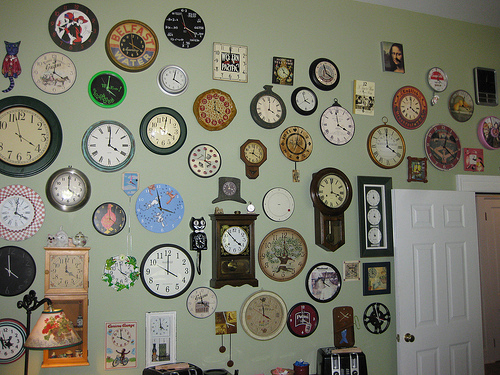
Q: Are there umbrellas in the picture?
A: No, there are no umbrellas.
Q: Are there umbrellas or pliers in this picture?
A: No, there are no umbrellas or pliers.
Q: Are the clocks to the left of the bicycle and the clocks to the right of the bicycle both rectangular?
A: Yes, both the clocks and the clocks are rectangular.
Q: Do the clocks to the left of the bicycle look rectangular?
A: Yes, the clocks are rectangular.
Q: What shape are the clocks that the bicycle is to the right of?
A: The clocks are rectangular.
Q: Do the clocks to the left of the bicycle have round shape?
A: No, the clocks are rectangular.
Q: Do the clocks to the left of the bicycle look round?
A: No, the clocks are rectangular.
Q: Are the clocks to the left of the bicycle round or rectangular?
A: The clocks are rectangular.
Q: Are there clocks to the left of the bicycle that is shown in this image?
A: Yes, there are clocks to the left of the bicycle.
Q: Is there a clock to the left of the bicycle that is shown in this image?
A: Yes, there are clocks to the left of the bicycle.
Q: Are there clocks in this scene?
A: Yes, there is a clock.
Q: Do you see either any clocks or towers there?
A: Yes, there is a clock.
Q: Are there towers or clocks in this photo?
A: Yes, there is a clock.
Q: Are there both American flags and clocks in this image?
A: No, there is a clock but no American flags.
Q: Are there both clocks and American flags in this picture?
A: No, there is a clock but no American flags.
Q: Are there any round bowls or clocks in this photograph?
A: Yes, there is a round clock.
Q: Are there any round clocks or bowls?
A: Yes, there is a round clock.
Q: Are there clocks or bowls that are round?
A: Yes, the clock is round.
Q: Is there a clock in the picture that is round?
A: Yes, there is a round clock.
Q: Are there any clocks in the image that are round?
A: Yes, there is a clock that is round.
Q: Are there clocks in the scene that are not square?
A: Yes, there is a round clock.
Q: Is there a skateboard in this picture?
A: No, there are no skateboards.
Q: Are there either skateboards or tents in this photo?
A: No, there are no skateboards or tents.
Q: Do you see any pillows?
A: No, there are no pillows.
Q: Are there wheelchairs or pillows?
A: No, there are no pillows or wheelchairs.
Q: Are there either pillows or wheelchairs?
A: No, there are no pillows or wheelchairs.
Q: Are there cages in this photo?
A: No, there are no cages.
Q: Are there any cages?
A: No, there are no cages.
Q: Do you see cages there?
A: No, there are no cages.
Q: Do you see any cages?
A: No, there are no cages.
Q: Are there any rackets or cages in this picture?
A: No, there are no cages or rackets.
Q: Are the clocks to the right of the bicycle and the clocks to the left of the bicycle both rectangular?
A: Yes, both the clocks and the clocks are rectangular.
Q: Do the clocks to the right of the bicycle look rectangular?
A: Yes, the clocks are rectangular.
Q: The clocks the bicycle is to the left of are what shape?
A: The clocks are rectangular.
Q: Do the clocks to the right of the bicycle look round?
A: No, the clocks are rectangular.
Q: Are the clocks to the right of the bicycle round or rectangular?
A: The clocks are rectangular.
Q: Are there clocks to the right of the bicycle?
A: Yes, there are clocks to the right of the bicycle.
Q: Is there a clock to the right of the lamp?
A: Yes, there are clocks to the right of the lamp.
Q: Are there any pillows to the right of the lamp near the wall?
A: No, there are clocks to the right of the lamp.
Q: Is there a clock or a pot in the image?
A: Yes, there is a clock.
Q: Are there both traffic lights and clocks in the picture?
A: No, there is a clock but no traffic lights.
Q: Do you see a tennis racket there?
A: No, there are no rackets.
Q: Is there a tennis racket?
A: No, there are no rackets.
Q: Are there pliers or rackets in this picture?
A: No, there are no rackets or pliers.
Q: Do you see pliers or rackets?
A: No, there are no rackets or pliers.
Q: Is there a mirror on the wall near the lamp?
A: No, there is a clock on the wall.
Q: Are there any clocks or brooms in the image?
A: Yes, there is a clock.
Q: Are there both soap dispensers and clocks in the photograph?
A: No, there is a clock but no soap dispensers.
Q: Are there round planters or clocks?
A: Yes, there is a round clock.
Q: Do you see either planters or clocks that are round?
A: Yes, the clock is round.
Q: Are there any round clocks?
A: Yes, there is a round clock.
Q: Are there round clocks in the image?
A: Yes, there is a round clock.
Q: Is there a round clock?
A: Yes, there is a round clock.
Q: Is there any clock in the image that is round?
A: Yes, there is a clock that is round.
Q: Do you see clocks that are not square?
A: Yes, there is a round clock.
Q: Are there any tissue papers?
A: No, there are no tissue papers.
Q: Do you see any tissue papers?
A: No, there are no tissue papers.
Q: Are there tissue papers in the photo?
A: No, there are no tissue papers.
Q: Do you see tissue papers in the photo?
A: No, there are no tissue papers.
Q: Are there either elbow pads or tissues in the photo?
A: No, there are no tissues or elbow pads.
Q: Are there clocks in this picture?
A: Yes, there is a clock.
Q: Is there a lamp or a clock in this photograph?
A: Yes, there is a clock.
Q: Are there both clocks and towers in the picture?
A: No, there is a clock but no towers.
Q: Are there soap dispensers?
A: No, there are no soap dispensers.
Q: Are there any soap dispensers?
A: No, there are no soap dispensers.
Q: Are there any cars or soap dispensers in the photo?
A: No, there are no soap dispensers or cars.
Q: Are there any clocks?
A: Yes, there is a clock.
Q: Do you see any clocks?
A: Yes, there is a clock.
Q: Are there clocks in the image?
A: Yes, there is a clock.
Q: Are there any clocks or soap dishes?
A: Yes, there is a clock.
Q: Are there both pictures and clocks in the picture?
A: Yes, there are both a clock and a picture.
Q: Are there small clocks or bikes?
A: Yes, there is a small clock.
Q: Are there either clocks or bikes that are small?
A: Yes, the clock is small.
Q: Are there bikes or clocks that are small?
A: Yes, the clock is small.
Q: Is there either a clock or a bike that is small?
A: Yes, the clock is small.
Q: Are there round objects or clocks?
A: Yes, there is a round clock.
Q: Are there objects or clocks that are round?
A: Yes, the clock is round.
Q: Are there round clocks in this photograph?
A: Yes, there is a round clock.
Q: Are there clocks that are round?
A: Yes, there is a clock that is round.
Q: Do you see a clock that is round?
A: Yes, there is a clock that is round.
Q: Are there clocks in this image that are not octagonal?
A: Yes, there is an round clock.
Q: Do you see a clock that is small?
A: Yes, there is a small clock.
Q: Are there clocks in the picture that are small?
A: Yes, there is a clock that is small.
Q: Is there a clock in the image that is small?
A: Yes, there is a clock that is small.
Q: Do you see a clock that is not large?
A: Yes, there is a small clock.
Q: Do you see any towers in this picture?
A: No, there are no towers.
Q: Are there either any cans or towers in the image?
A: No, there are no towers or cans.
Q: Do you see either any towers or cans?
A: No, there are no towers or cans.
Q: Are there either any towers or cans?
A: No, there are no towers or cans.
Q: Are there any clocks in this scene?
A: Yes, there is a clock.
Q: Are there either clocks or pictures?
A: Yes, there is a clock.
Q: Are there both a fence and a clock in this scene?
A: No, there is a clock but no fences.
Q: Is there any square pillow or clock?
A: Yes, there is a square clock.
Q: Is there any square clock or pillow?
A: Yes, there is a square clock.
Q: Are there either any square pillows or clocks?
A: Yes, there is a square clock.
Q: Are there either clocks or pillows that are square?
A: Yes, the clock is square.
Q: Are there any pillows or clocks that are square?
A: Yes, the clock is square.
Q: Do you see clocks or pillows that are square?
A: Yes, the clock is square.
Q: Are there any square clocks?
A: Yes, there is a square clock.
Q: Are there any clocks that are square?
A: Yes, there is a clock that is square.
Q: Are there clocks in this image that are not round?
A: Yes, there is a square clock.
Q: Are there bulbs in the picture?
A: No, there are no bulbs.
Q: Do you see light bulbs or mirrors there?
A: No, there are no light bulbs or mirrors.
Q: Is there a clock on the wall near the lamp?
A: Yes, there is a clock on the wall.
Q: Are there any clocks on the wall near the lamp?
A: Yes, there is a clock on the wall.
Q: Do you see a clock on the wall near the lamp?
A: Yes, there is a clock on the wall.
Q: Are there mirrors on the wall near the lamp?
A: No, there is a clock on the wall.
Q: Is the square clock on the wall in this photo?
A: Yes, the clock is on the wall.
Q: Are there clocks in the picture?
A: Yes, there is a clock.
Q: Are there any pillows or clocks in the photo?
A: Yes, there is a clock.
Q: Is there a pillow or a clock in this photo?
A: Yes, there is a clock.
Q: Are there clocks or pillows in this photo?
A: Yes, there is a clock.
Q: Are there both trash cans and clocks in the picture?
A: No, there is a clock but no trash cans.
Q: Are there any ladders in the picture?
A: No, there are no ladders.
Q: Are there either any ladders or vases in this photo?
A: No, there are no ladders or vases.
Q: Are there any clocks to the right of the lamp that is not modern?
A: Yes, there is a clock to the right of the lamp.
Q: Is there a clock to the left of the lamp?
A: No, the clock is to the right of the lamp.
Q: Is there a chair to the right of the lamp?
A: No, there is a clock to the right of the lamp.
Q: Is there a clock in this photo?
A: Yes, there is a clock.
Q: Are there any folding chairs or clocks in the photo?
A: Yes, there is a clock.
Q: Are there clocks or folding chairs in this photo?
A: Yes, there is a clock.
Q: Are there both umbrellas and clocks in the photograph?
A: No, there is a clock but no umbrellas.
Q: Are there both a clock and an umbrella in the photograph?
A: No, there is a clock but no umbrellas.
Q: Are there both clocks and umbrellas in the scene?
A: No, there is a clock but no umbrellas.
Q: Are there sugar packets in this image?
A: No, there are no sugar packets.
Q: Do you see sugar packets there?
A: No, there are no sugar packets.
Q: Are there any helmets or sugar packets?
A: No, there are no sugar packets or helmets.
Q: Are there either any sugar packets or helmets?
A: No, there are no sugar packets or helmets.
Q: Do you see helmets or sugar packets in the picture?
A: No, there are no sugar packets or helmets.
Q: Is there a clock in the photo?
A: Yes, there is a clock.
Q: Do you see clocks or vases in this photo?
A: Yes, there is a clock.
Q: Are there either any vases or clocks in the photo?
A: Yes, there is a clock.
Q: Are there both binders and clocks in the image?
A: No, there is a clock but no binders.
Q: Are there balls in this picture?
A: No, there are no balls.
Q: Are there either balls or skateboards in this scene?
A: No, there are no balls or skateboards.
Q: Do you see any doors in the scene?
A: Yes, there is a door.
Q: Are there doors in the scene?
A: Yes, there is a door.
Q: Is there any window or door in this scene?
A: Yes, there is a door.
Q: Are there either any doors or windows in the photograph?
A: Yes, there is a door.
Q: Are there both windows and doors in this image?
A: No, there is a door but no windows.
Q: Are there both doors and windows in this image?
A: No, there is a door but no windows.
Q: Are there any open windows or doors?
A: Yes, there is an open door.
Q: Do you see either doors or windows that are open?
A: Yes, the door is open.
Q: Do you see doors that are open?
A: Yes, there is an open door.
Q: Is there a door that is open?
A: Yes, there is a door that is open.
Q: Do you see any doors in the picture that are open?
A: Yes, there is a door that is open.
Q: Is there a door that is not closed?
A: Yes, there is a open door.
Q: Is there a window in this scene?
A: No, there are no windows.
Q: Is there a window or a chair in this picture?
A: No, there are no windows or chairs.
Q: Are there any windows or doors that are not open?
A: No, there is a door but it is open.